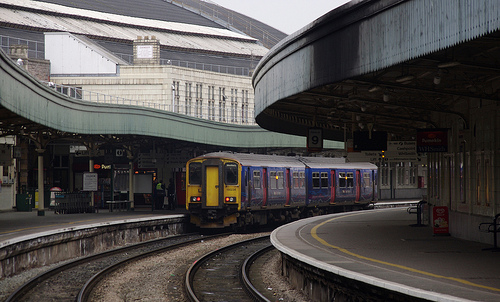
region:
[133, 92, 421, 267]
train on train tracks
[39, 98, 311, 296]
train tracks with train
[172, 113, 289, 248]
back of train is yellow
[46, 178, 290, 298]
two train tracks next to each other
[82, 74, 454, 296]
train going through station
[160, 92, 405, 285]
train during the day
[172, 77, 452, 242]
a short train on tracks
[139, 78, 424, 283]
a short train during the day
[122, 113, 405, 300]
a short train going through station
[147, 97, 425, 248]
a short train with lights on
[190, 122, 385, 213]
A subway on the tracks.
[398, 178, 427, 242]
A bench at the station.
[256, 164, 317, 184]
Windows are on the train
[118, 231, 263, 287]
The tracks are black and dirty.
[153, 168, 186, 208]
People standing in the train station.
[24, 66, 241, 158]
The edge of the roof is green.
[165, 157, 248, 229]
The train is yellow in the front.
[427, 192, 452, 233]
A red posterboard sits on the station walkway.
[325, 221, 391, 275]
A yellow line of the edge of the sidewalk.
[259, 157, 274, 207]
The train has red doors.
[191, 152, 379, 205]
Small train on tracks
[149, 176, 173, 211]
person standing on the train platform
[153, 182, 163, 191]
person wearing a green vest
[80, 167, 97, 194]
sign on train platform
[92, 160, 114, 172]
red and white sign on train platform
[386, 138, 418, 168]
sign hanging from the ceiling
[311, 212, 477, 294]
yellow line painted on train platform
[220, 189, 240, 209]
red and white lights on train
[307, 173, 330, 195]
windows on the train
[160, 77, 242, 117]
windows on white building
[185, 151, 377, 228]
a blue red and yellow train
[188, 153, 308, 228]
the rear car of a train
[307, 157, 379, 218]
the front car of a train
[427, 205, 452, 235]
a red and white street sign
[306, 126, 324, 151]
black and white 9 sign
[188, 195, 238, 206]
rear lights of a train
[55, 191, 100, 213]
a long metal bench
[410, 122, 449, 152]
a sign hanging from a ceiling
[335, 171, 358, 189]
a train's passenger window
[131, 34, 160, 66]
a brick chimney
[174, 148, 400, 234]
Red and silver train with yellow on the back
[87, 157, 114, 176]
red and white sign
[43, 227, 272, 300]
two sets of train tracks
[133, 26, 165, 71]
Chimney with white patch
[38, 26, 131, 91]
White section of building that is angled down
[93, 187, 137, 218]
Black bench for waiting passengers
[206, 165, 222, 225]
Door on train is yellow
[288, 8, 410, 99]
Black spot on building on right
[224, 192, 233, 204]
Little orange lights on back of train